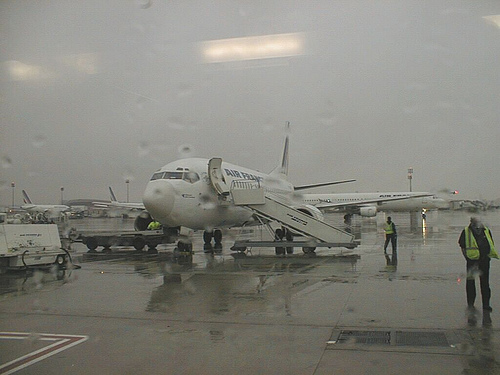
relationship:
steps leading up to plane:
[222, 180, 359, 253] [91, 119, 433, 263]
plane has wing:
[91, 119, 433, 263] [287, 191, 438, 210]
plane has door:
[91, 119, 433, 263] [210, 157, 231, 197]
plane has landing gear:
[91, 119, 433, 263] [176, 222, 298, 254]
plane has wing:
[91, 119, 433, 263] [92, 194, 152, 213]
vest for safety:
[461, 225, 497, 258] [459, 222, 497, 260]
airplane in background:
[289, 188, 450, 223] [1, 179, 498, 236]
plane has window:
[91, 119, 433, 263] [163, 167, 182, 179]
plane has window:
[91, 119, 433, 263] [150, 172, 163, 181]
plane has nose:
[91, 119, 433, 263] [142, 179, 177, 219]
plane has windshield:
[91, 119, 433, 263] [163, 167, 182, 179]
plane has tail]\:
[91, 119, 433, 263] [280, 116, 296, 178]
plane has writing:
[91, 119, 433, 263] [224, 166, 266, 185]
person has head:
[456, 210, 497, 312] [463, 213, 485, 231]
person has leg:
[456, 210, 497, 312] [478, 256, 497, 314]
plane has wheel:
[91, 119, 433, 263] [213, 225, 225, 241]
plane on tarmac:
[91, 119, 433, 263] [0, 209, 499, 373]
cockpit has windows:
[145, 159, 202, 191] [163, 167, 182, 179]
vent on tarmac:
[334, 324, 392, 346] [0, 209, 499, 373]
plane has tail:
[91, 119, 433, 263] [263, 120, 296, 186]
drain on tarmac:
[389, 326, 452, 352] [0, 209, 499, 373]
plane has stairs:
[91, 119, 433, 263] [222, 180, 359, 253]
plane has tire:
[91, 119, 433, 263] [201, 226, 208, 244]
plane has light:
[91, 119, 433, 263] [449, 188, 461, 195]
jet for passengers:
[18, 189, 72, 217] [26, 208, 62, 215]